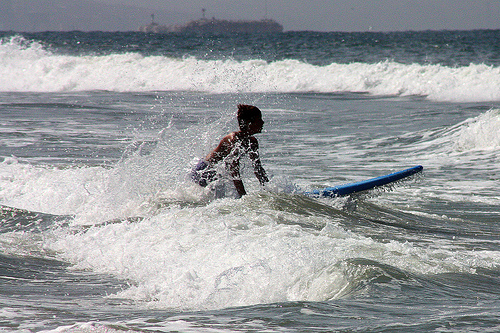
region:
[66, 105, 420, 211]
a boy riding a surfboard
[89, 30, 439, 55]
choppy blue waters behind the waves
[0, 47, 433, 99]
white ocean foam from a rolling wave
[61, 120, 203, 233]
ocean spray behind the surfboard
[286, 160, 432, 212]
blue front end of the surboard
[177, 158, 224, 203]
the boy's blue board shorts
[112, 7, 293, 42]
an island in the distance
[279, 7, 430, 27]
clear blue skies over the ocean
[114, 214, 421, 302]
a low rolling wave in the foreground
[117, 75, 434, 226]
a boy on a blue surfboard on the water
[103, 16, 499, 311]
a man on a surfboard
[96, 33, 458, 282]
a man on a blue surfboard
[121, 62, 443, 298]
a man ridng a surfboard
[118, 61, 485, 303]
a man in the water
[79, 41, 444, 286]
a surfboard with a man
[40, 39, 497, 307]
a surfer riding a surfboard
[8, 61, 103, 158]
a body of water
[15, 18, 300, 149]
a body of wavy water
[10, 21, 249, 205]
a body of water with waves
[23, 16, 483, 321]
a surfer riding a wave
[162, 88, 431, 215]
boy riding a wave on a surfboard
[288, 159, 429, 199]
front of blue surfboard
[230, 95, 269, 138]
boy with dark hair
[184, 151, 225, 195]
purple swim suit worn by boy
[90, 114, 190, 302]
white water created by waves crashing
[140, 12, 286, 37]
large freighter in the distance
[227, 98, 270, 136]
boy's hair blowing in the wind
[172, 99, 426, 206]
boy holding edges of surfboard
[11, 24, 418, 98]
swell about to break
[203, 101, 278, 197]
boy with tanned skin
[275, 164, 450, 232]
the surfboard is blue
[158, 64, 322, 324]
the boy is surfing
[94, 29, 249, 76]
the water is blue green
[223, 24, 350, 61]
the water is blue green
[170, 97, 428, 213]
The boy is on a surfboard.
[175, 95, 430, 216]
The surfboard is blue.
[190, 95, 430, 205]
The surfboard is wet.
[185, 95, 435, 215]
The surfboard is in the water.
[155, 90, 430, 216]
The boy is wet.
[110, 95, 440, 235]
The water is splashing.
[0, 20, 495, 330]
The water is zealous.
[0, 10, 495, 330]
The water is rambunctious.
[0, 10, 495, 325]
The water is tumultuos.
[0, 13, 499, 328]
The water is boisterous.